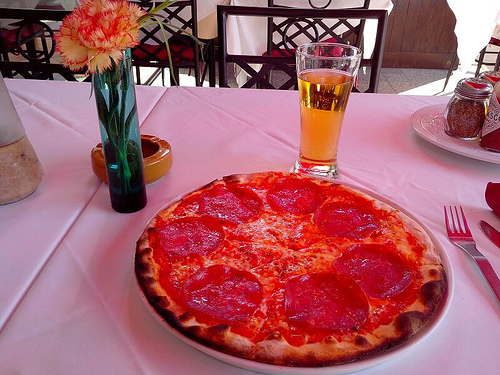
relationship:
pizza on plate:
[133, 170, 447, 369] [131, 169, 456, 374]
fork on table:
[441, 205, 500, 300] [0, 74, 499, 375]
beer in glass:
[294, 63, 356, 166] [293, 38, 365, 180]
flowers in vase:
[54, 0, 148, 77] [90, 42, 149, 215]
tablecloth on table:
[0, 72, 499, 374] [0, 74, 499, 375]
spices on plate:
[444, 70, 499, 154] [407, 94, 499, 166]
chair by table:
[213, 2, 390, 98] [0, 74, 499, 375]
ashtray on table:
[84, 123, 177, 193] [0, 74, 499, 375]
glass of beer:
[293, 38, 365, 180] [294, 63, 356, 166]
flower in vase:
[54, 0, 148, 77] [90, 42, 149, 215]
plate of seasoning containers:
[407, 94, 499, 166] [444, 70, 499, 154]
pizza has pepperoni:
[133, 170, 447, 369] [154, 176, 418, 334]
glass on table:
[293, 38, 365, 180] [0, 74, 499, 375]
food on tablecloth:
[133, 170, 447, 369] [0, 72, 499, 374]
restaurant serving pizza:
[0, 1, 499, 374] [133, 170, 447, 369]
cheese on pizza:
[160, 171, 424, 346] [133, 170, 447, 369]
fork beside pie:
[441, 205, 500, 300] [133, 170, 447, 369]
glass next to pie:
[293, 38, 365, 180] [133, 170, 447, 369]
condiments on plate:
[444, 70, 499, 154] [407, 94, 499, 166]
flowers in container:
[54, 0, 148, 77] [90, 42, 149, 215]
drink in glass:
[294, 63, 356, 166] [293, 38, 365, 180]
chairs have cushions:
[0, 1, 399, 95] [123, 32, 347, 64]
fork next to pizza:
[441, 205, 500, 300] [133, 170, 447, 369]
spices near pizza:
[444, 70, 499, 154] [133, 170, 447, 369]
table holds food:
[0, 74, 499, 375] [133, 170, 447, 369]